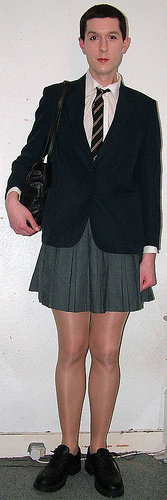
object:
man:
[3, 3, 164, 498]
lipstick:
[95, 53, 110, 63]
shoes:
[39, 444, 83, 490]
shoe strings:
[84, 440, 123, 496]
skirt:
[28, 219, 155, 314]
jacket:
[4, 73, 164, 255]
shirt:
[3, 69, 164, 257]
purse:
[20, 80, 70, 228]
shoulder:
[34, 80, 72, 125]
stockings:
[52, 309, 129, 455]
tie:
[89, 86, 112, 163]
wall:
[0, 1, 166, 449]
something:
[0, 443, 164, 472]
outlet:
[25, 432, 48, 474]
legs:
[48, 305, 89, 458]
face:
[84, 10, 124, 74]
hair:
[78, 4, 127, 39]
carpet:
[0, 448, 167, 500]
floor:
[0, 452, 166, 499]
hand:
[4, 191, 39, 242]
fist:
[137, 253, 157, 310]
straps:
[39, 80, 70, 162]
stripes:
[92, 93, 105, 161]